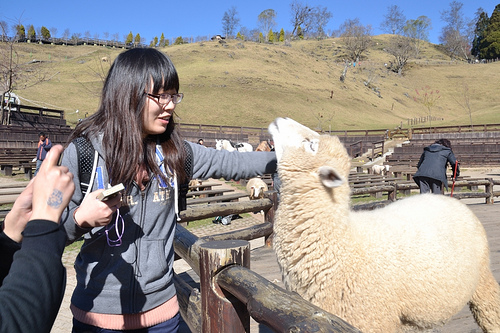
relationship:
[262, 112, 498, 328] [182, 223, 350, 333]
sheep inside gate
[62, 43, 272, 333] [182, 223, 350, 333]
girl inside gate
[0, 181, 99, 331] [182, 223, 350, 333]
black jacket inside gate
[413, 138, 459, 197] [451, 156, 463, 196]
person using shovel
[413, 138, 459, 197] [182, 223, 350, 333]
person inside gate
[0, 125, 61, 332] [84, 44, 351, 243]
person taking picture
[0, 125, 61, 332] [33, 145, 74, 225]
person has stamp on hand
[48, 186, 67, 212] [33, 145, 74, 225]
stamp on on hand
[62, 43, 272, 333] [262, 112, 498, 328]
girl with sheep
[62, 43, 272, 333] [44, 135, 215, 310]
girl with grey coat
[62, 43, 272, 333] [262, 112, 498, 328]
girl petting sheep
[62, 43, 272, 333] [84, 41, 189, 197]
girl with black hair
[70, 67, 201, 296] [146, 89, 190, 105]
girl with glasses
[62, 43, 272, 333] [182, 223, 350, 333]
girl outside gate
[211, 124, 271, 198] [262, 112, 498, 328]
group of sheep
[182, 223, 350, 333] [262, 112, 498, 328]
gate to keep sheep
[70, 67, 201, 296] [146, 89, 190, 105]
girl wearing glasses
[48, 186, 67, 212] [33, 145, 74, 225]
tattoo on hand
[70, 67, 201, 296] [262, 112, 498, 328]
girl petting sheep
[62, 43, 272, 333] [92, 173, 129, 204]
girl holding phone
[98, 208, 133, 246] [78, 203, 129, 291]
earbuds in pocket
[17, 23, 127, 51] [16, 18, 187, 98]
bridge in background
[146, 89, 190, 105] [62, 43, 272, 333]
glasses on girl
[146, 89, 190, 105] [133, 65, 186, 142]
glasses on face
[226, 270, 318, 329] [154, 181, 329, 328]
wood rail on fence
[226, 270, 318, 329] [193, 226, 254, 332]
wooden fence post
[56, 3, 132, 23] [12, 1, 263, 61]
blue sky above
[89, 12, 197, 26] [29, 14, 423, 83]
sky above hillside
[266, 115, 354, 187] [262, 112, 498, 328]
head of sheep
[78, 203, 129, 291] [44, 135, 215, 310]
pocket on jacket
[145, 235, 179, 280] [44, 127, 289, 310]
pocket on grey coat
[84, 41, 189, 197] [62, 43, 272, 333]
hair on girl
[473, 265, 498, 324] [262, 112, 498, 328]
leg of sheep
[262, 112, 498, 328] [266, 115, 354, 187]
sheep lifting head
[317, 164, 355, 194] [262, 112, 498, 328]
ear of sheep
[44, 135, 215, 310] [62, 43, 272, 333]
jacket on girl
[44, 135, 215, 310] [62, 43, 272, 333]
sweatshirt on girl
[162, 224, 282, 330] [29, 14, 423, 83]
fence on hillside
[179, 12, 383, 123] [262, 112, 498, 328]
hill above sheep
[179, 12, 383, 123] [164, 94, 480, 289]
hill above sheep pen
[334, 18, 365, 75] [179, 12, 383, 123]
tree on hill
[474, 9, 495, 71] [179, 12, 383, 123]
pine tree on hill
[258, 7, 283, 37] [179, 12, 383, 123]
tree on hill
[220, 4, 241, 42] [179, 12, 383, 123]
tree on hill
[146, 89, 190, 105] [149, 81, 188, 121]
glasses over eyes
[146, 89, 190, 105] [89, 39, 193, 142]
glasses over woman's eyes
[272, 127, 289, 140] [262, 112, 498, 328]
white tan sheep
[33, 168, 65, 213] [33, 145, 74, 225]
back of hand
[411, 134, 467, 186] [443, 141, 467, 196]
person a sweeping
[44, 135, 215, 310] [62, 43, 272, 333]
hoodie on girl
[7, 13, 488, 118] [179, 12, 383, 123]
large brown hill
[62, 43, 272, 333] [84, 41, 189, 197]
girl with hair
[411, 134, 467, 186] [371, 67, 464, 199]
person in distance